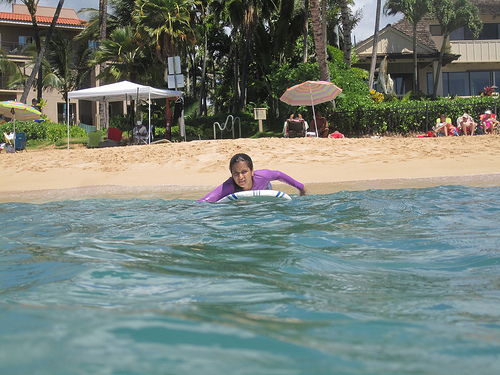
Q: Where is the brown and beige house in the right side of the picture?
A: Near green hedges.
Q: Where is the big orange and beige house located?
A: Near a yellow and white umbrella.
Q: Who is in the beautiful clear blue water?
A: Woman wearing purple top with blue and white surfboard.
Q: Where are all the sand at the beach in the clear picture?
A: Front of people.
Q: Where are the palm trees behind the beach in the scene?
A: Near a white covered ten.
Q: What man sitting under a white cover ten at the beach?
A: Man near the sand.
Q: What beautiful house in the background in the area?
A: House near group of people.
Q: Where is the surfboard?
A: In the water.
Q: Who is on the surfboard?
A: The woman.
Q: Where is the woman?
A: On the surfboard.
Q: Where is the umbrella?
A: On the beach.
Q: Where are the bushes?
A: Behind the people.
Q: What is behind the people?
A: Bushes.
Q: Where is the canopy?
A: Above the people.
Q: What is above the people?
A: A canopy.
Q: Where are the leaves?
A: On the trees.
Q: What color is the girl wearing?
A: Purple.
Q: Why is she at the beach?
A: To surf.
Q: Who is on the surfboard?
A: The girl.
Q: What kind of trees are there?
A: Palm.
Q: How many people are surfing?
A: One.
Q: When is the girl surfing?
A: Daytime.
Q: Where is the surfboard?
A: Under the girl.